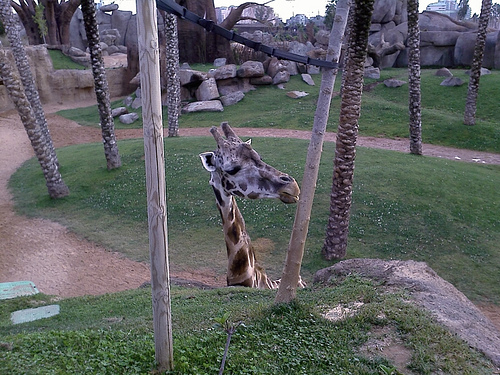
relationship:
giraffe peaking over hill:
[197, 122, 304, 290] [1, 258, 498, 373]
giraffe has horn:
[197, 122, 304, 290] [208, 124, 229, 150]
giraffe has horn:
[197, 122, 304, 290] [221, 119, 239, 141]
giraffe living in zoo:
[197, 122, 304, 290] [0, 0, 498, 373]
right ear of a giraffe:
[195, 146, 221, 175] [197, 122, 304, 290]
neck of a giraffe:
[209, 187, 260, 288] [197, 122, 304, 290]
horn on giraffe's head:
[208, 126, 227, 150] [198, 119, 303, 211]